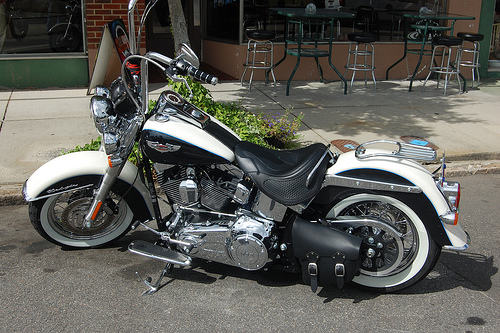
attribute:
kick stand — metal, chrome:
[135, 259, 171, 298]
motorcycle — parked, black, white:
[25, 2, 471, 306]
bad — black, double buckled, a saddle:
[292, 216, 363, 294]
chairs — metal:
[244, 29, 485, 97]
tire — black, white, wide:
[27, 177, 139, 250]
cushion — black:
[235, 138, 331, 203]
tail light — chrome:
[437, 176, 461, 226]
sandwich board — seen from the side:
[88, 16, 146, 96]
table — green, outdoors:
[265, 6, 355, 100]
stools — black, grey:
[424, 33, 487, 93]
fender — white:
[23, 146, 156, 216]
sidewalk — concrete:
[1, 78, 500, 205]